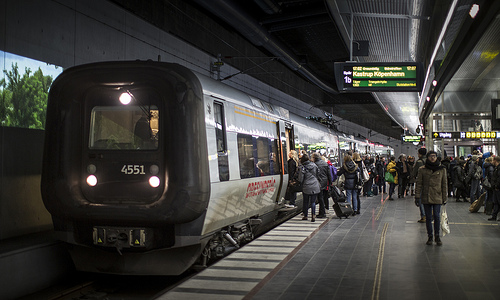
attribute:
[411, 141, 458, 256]
person — standing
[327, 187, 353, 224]
bag — purple 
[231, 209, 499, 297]
platform — dark grey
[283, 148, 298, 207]
woman — blond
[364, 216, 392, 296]
stripe — yellow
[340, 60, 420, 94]
sign — green , yellow 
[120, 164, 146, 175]
numbers — white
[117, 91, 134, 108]
light —  train's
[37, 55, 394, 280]
train — black, grey , silver , w/ open door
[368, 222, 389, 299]
lines — yellow 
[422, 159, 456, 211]
jacket — brown , polyester 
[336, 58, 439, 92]
sign —  for train's arrival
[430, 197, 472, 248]
bag — white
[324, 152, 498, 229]
people — standing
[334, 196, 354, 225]
suit case — black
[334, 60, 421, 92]
sign — green, yellow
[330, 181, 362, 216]
luggage — black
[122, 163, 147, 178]
numbers — white, 4551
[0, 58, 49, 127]
trees — green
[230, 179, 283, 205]
logo — red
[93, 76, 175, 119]
light — bright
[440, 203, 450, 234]
bag —  white